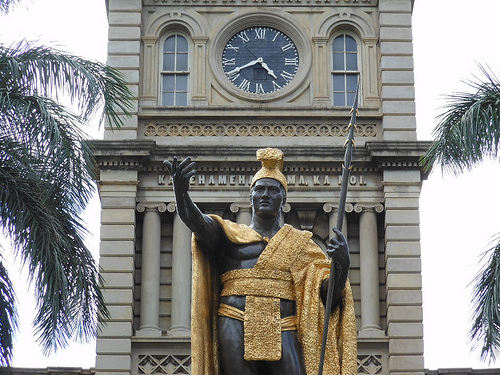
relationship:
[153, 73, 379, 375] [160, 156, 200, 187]
statue with hand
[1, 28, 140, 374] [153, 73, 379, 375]
tree beside statue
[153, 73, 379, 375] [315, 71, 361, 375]
statue holding weapon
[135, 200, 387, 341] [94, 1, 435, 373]
columns on building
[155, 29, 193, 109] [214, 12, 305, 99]
window by clock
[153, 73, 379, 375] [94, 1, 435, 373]
statue by building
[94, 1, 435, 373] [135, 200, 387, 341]
building has columns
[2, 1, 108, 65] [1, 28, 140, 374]
sky above tree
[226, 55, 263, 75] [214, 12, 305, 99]
hand on clock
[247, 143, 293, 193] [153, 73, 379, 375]
head band on statue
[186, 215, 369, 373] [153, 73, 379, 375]
robe on statue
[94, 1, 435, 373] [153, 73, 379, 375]
building behind statue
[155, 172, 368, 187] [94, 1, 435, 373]
words on building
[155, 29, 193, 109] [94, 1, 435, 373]
window on building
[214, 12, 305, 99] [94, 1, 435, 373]
clock on building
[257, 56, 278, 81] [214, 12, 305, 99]
hand on clock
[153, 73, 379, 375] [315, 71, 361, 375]
statue with weapon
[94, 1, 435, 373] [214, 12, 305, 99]
building with clock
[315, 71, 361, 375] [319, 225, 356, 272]
weapon in hand